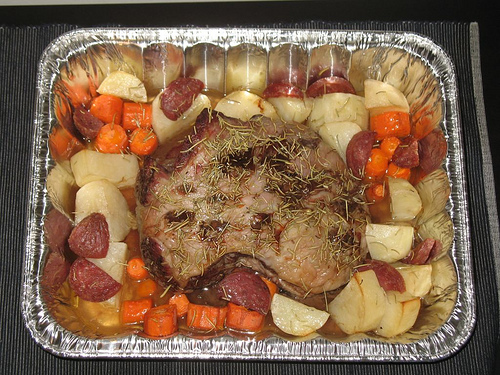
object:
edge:
[396, 296, 421, 335]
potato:
[328, 269, 390, 336]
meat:
[219, 267, 271, 317]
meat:
[68, 256, 122, 302]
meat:
[68, 212, 110, 258]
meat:
[160, 76, 205, 121]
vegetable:
[225, 302, 264, 331]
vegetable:
[143, 304, 178, 337]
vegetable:
[364, 79, 410, 117]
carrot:
[370, 111, 411, 141]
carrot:
[187, 303, 227, 331]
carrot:
[129, 127, 158, 156]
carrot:
[90, 94, 124, 125]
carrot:
[126, 257, 148, 279]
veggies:
[95, 70, 147, 103]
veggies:
[150, 88, 210, 146]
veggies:
[214, 90, 281, 122]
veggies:
[268, 97, 314, 124]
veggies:
[306, 92, 369, 133]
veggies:
[318, 121, 362, 164]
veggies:
[388, 176, 423, 221]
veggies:
[365, 223, 414, 263]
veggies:
[385, 261, 433, 304]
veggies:
[372, 290, 421, 338]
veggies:
[84, 242, 130, 309]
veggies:
[75, 180, 132, 242]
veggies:
[122, 103, 152, 134]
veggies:
[95, 123, 127, 154]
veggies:
[379, 135, 402, 162]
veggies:
[386, 162, 412, 181]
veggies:
[364, 148, 389, 182]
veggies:
[364, 182, 387, 204]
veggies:
[260, 276, 280, 299]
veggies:
[169, 294, 191, 318]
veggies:
[123, 298, 154, 326]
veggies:
[136, 278, 157, 297]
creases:
[41, 335, 467, 363]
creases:
[19, 31, 68, 357]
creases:
[49, 27, 435, 43]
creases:
[442, 46, 477, 359]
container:
[19, 27, 476, 362]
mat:
[0, 21, 500, 375]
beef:
[134, 107, 372, 298]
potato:
[270, 293, 331, 337]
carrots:
[90, 94, 159, 155]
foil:
[52, 44, 442, 99]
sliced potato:
[70, 150, 140, 189]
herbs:
[111, 84, 416, 311]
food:
[68, 70, 436, 337]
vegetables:
[85, 241, 178, 337]